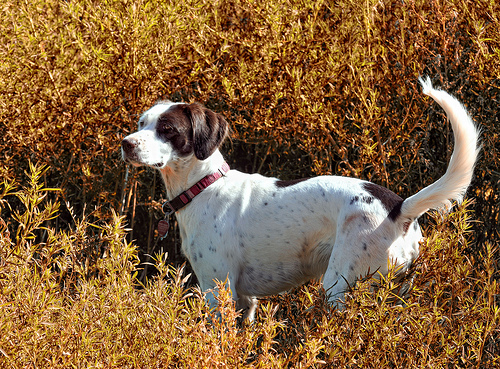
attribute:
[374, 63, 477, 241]
tail — dog's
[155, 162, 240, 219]
collar — red, dog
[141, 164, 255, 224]
collar — dog, idenification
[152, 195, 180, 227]
tags — ID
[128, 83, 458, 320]
dog — one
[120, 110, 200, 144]
eyes — canine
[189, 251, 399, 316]
legs — canine, hidden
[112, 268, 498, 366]
grass — tall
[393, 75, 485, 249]
tail — canine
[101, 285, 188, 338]
leaves — some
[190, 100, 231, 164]
ear — canine, one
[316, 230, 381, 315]
leg — one, canine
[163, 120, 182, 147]
eye — one, canine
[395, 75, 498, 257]
tail — one, canine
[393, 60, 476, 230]
tail — canine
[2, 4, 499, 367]
grass — tall, brown, green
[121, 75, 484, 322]
dog — white, black spotted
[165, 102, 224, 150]
spot —  large and black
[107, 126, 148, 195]
nose —  black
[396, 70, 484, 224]
tail — curved, white